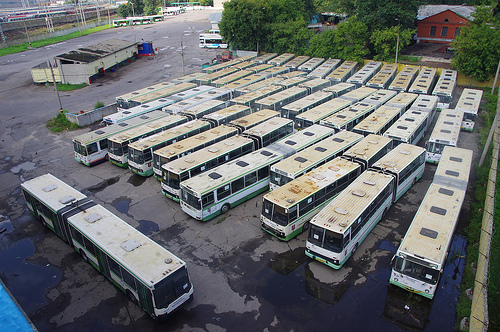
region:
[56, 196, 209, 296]
the top of a bus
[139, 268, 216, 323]
the windshield on a bus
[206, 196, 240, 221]
the wheel ona bus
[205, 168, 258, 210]
side windows ona bus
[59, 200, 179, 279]
a white top on a bus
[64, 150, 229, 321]
a bus in a parking lot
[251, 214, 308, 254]
the headlight on a bus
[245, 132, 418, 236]
buses side by side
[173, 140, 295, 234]
a white and green bus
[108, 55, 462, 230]
lots of buses in a parkinlot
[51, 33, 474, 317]
the buses are parked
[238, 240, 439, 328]
big puddle of water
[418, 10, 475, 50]
the house is red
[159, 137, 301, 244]
the bus is green and white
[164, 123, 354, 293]
the bus is green and white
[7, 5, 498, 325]
picture taken outdoors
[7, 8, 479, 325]
picture taken during the day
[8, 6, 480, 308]
various busses in a lot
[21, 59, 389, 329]
the busses are not moving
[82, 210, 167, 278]
the bus is white on top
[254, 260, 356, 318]
he ground is partially wet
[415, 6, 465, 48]
the house is red in color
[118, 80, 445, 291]
the busses are lined up in a row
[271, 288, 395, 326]
a large water puddle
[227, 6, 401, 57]
trees behind the busses